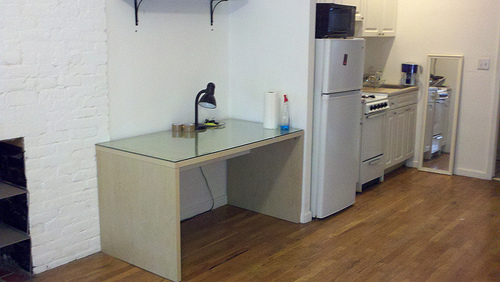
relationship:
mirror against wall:
[411, 40, 479, 205] [401, 2, 498, 180]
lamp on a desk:
[192, 79, 219, 134] [89, 113, 306, 280]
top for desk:
[98, 118, 302, 165] [89, 113, 306, 280]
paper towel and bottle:
[263, 90, 278, 130] [281, 95, 288, 131]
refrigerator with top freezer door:
[306, 35, 373, 238] [310, 29, 380, 101]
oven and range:
[358, 90, 395, 190] [363, 87, 388, 105]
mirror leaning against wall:
[417, 54, 462, 176] [401, 2, 498, 180]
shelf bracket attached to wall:
[129, 0, 144, 33] [3, 10, 229, 192]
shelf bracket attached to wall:
[207, 0, 226, 28] [3, 10, 229, 192]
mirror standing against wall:
[417, 54, 462, 176] [423, 0, 485, 174]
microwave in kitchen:
[314, 0, 375, 50] [303, 3, 498, 231]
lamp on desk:
[194, 82, 218, 131] [89, 113, 306, 280]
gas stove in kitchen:
[358, 91, 389, 192] [303, 3, 498, 231]